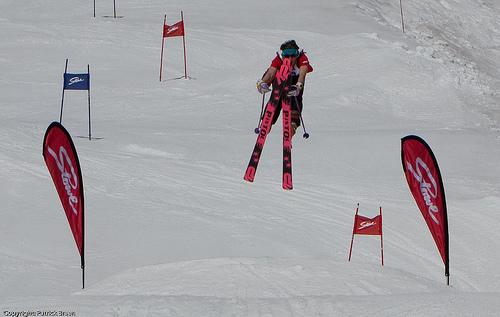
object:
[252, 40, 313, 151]
person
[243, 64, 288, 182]
ski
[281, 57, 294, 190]
ski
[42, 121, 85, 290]
flag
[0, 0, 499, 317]
snow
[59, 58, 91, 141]
track advertisement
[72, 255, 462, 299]
pile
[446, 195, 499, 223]
pile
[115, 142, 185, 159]
pile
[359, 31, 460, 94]
pile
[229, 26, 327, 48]
pile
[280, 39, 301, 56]
hair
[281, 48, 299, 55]
headband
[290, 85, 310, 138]
ski pole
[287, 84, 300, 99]
hand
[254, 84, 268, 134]
ski pole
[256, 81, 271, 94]
hand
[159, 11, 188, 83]
flag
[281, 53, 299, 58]
sunglasses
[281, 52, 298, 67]
face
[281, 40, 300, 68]
head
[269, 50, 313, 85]
shirt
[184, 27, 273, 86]
track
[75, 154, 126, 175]
track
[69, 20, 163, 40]
track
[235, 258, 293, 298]
track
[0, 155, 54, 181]
track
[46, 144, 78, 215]
writing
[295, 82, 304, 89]
wrist band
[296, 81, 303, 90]
wrist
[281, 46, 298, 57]
forehead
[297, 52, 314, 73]
sleeve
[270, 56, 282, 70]
sleeve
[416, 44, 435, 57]
cluster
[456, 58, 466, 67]
cluster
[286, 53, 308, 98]
arm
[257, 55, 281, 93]
arm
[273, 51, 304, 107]
body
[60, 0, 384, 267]
series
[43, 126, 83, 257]
fabric